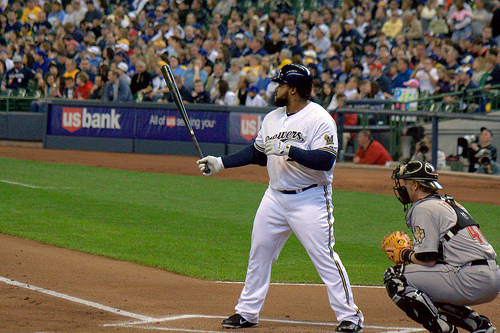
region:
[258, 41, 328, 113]
the helmet is black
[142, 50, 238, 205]
the player is holding a bat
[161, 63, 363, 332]
Prince Fielder in the batter's box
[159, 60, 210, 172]
a black wood baseball bat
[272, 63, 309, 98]
dark blue batter's helmet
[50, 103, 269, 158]
USBank ads on the side of the field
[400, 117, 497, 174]
photographers in the camera well.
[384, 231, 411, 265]
catcher's mitt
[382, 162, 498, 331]
a catcher crouched behind home plate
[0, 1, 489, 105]
a large crowd of fans in the stands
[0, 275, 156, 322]
white chalk first base line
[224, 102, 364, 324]
white home uniform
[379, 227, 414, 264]
catcher with light brown mitt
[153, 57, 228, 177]
black bat in batter's right hand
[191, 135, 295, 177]
batter in white gloves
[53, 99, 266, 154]
US Bank ad on blue tarp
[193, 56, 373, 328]
batter standing sideways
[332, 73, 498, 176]
metal railing surrounding dugout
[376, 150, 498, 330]
catcher in crouched position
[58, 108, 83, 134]
red shield on blue tarp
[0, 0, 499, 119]
spectators watching baseball game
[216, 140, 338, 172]
navy blue sleeves under white shirt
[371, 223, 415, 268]
leather catcher's mitt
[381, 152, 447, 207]
catcher's helmet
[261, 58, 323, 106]
black baseball helmet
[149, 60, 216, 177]
black wooden baseball bat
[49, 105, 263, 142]
blue sponser banner on side of baseball field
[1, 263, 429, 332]
white lines drawn on baseball field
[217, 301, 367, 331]
black and white nike cleats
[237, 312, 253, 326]
white nike logo on side of shoe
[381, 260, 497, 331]
knee and leg guard on catcher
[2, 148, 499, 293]
green grass on baseball field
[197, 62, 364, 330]
Batter wearing black helmet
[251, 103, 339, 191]
Batter wearing white shirt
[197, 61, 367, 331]
Batter wearing white pants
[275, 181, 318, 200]
Brown belt on white pants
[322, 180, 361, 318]
Stripe running along white pants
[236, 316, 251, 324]
White Nike logo on black shoe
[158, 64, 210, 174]
Wooden bat is black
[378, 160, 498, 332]
Catcher crouching down behind batter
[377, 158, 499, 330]
Catcher wearing leather glove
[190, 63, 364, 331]
Batter has black beard